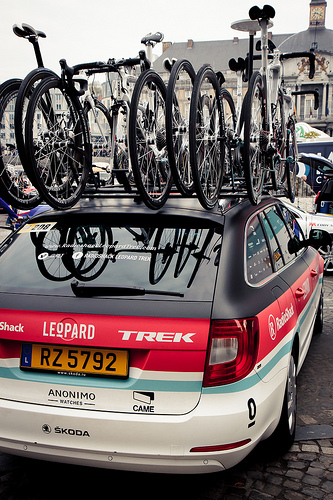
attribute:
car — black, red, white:
[0, 178, 326, 486]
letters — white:
[33, 237, 191, 270]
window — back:
[3, 223, 228, 308]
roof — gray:
[151, 25, 332, 70]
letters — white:
[265, 300, 295, 340]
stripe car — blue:
[166, 374, 263, 398]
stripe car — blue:
[252, 334, 310, 350]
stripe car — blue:
[11, 365, 207, 406]